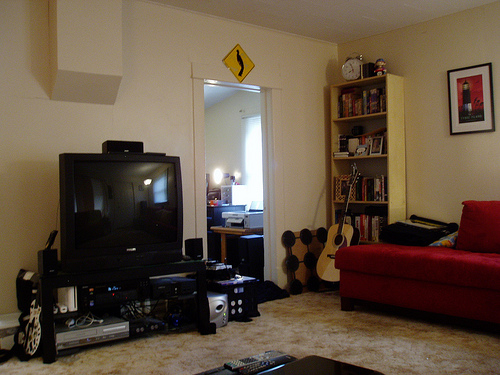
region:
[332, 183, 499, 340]
Red couch against the wall.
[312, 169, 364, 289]
Guitar beside couch.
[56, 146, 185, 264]
black television on stand.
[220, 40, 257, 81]
sign above the door.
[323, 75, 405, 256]
bookshelf against the wall.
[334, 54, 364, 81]
clock on top of bookshelf.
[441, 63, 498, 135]
Picture on the wall.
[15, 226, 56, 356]
Electric guitar by television.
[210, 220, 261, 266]
Table in the kitchen.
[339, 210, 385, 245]
Books on the shelf.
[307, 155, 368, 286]
a wooden acoustic guitar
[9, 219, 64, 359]
an electric guitar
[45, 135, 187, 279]
a television set on stand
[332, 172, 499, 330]
a red couch on carpet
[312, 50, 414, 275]
a four layer book shelf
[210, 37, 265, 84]
a sign on the wall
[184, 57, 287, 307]
an entrance to a room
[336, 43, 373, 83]
clock on top of shelf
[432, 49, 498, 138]
a painting on the wall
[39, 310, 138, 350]
a dvd player set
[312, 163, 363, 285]
guitar in the corner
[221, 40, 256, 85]
sign on the wall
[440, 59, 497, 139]
picture on the wall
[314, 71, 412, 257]
bookshelf in the corner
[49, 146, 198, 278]
black plastic tv on stand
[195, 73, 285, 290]
doorway between the rooms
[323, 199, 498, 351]
red couch in the room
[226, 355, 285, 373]
remote control on table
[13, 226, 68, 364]
white and black guitar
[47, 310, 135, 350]
silver plastic video player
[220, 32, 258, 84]
a yellow and black sign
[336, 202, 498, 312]
a red sofa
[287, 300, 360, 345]
beige carpet on the floor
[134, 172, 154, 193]
a light reflecting on the screen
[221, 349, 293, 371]
remotes on the coffee table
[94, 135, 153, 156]
a black cable box on the tv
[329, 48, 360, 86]
a large clock on a shelf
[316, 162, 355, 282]
an acoustic guitar next to the sofa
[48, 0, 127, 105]
an inset in the white wall